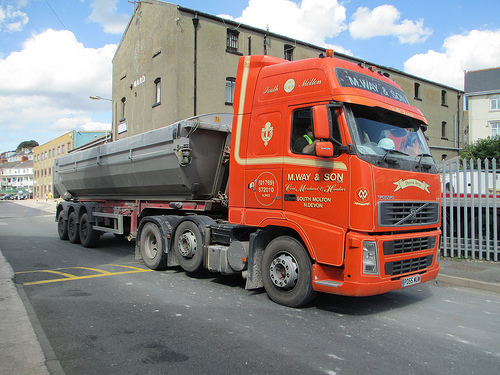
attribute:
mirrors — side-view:
[305, 100, 340, 163]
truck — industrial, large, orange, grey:
[42, 45, 463, 314]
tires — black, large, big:
[140, 222, 194, 271]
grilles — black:
[377, 199, 438, 275]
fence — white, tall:
[457, 151, 494, 266]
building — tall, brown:
[98, 4, 214, 106]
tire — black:
[256, 235, 306, 307]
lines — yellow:
[19, 261, 123, 280]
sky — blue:
[440, 6, 473, 25]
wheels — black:
[49, 206, 92, 245]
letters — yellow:
[284, 171, 346, 185]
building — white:
[464, 94, 495, 126]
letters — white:
[131, 75, 146, 85]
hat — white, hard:
[377, 134, 395, 153]